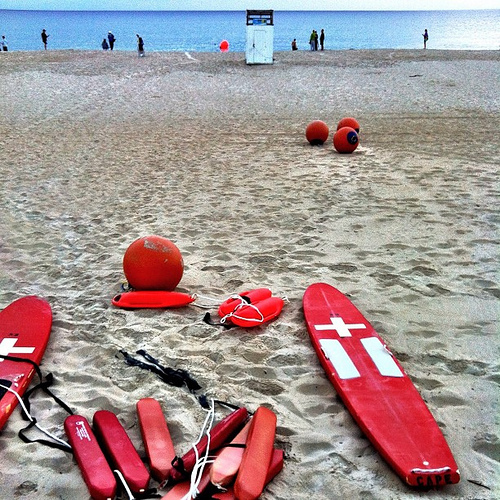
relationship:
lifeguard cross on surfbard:
[316, 316, 367, 339] [302, 281, 461, 491]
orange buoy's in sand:
[121, 236, 185, 292] [0, 53, 500, 291]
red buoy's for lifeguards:
[307, 118, 364, 156] [1, 236, 500, 499]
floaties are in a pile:
[65, 397, 286, 498] [283, 399, 487, 499]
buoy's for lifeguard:
[1, 119, 500, 500] [246, 8, 277, 65]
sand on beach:
[1, 51, 498, 499] [1, 1, 500, 498]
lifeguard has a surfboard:
[246, 8, 277, 65] [302, 281, 461, 491]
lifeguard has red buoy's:
[246, 8, 277, 65] [307, 118, 364, 156]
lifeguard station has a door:
[246, 8, 277, 65] [251, 28, 269, 64]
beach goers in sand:
[1, 28, 147, 55] [1, 51, 498, 499]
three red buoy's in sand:
[307, 118, 364, 156] [1, 51, 498, 499]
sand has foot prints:
[1, 51, 498, 499] [421, 349, 487, 378]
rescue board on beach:
[302, 281, 461, 491] [1, 1, 500, 498]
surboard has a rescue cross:
[302, 281, 461, 491] [316, 316, 367, 339]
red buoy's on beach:
[307, 118, 364, 156] [1, 1, 500, 498]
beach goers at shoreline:
[1, 28, 147, 55] [273, 42, 500, 60]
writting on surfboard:
[414, 472, 456, 490] [302, 281, 461, 491]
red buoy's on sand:
[307, 118, 364, 156] [1, 51, 498, 499]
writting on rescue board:
[414, 472, 456, 490] [302, 281, 461, 491]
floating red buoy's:
[307, 118, 364, 156] [121, 236, 185, 292]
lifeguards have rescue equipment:
[246, 8, 277, 65] [1, 236, 500, 499]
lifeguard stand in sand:
[246, 8, 277, 65] [1, 51, 498, 499]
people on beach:
[1, 28, 147, 55] [1, 1, 500, 498]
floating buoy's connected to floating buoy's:
[218, 296, 286, 331] [218, 296, 286, 331]